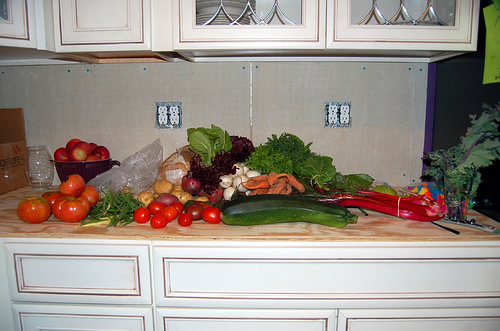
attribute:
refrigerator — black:
[433, 51, 498, 221]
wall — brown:
[1, 58, 421, 203]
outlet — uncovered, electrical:
[147, 97, 197, 135]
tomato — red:
[17, 197, 48, 222]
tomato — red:
[59, 175, 82, 195]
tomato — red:
[50, 195, 87, 220]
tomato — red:
[78, 182, 99, 205]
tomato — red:
[40, 188, 64, 210]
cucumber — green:
[228, 196, 350, 233]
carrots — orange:
[241, 163, 306, 207]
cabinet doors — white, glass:
[176, 0, 489, 57]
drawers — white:
[53, 222, 355, 327]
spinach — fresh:
[188, 119, 240, 175]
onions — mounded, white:
[227, 169, 255, 205]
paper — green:
[415, 161, 449, 208]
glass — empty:
[18, 141, 59, 186]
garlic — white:
[211, 155, 259, 190]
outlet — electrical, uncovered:
[323, 100, 353, 127]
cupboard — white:
[67, 9, 420, 67]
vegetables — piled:
[18, 130, 498, 237]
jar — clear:
[5, 122, 75, 210]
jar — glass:
[15, 132, 65, 196]